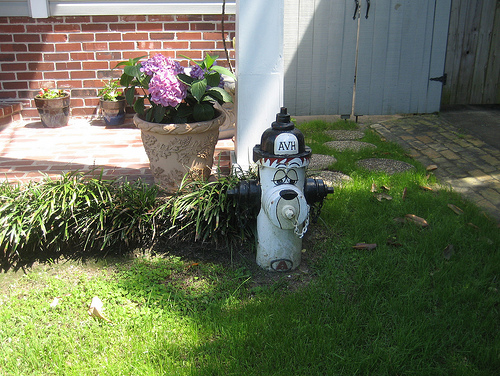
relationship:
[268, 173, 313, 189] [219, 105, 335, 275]
two eyes on fire hydrant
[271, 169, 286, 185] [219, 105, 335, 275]
eye on fire hydrant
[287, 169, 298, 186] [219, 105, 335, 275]
eye on fire hydrant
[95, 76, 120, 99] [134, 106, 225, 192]
plants in a pot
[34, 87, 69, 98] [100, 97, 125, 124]
plants in a pot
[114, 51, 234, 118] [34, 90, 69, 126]
plants in a pot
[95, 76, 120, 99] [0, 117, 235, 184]
plants on patio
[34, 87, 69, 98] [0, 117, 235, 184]
plants on patio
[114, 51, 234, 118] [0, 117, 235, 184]
plants on patio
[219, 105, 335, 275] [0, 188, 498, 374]
fire hydrant in grass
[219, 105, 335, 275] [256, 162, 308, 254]
fire hydrant painted like a dog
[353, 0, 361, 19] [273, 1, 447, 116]
handle on door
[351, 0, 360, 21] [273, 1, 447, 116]
handle on door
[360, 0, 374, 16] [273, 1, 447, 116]
handle on door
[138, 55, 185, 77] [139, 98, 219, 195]
flower in pot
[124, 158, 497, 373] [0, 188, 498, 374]
shadow in grass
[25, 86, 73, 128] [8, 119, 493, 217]
pot on patio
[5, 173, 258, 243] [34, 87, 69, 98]
bush behind plants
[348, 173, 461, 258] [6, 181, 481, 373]
leaves on ground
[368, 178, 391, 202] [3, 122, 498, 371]
dead leaves on grass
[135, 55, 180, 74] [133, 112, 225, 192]
flower in a planter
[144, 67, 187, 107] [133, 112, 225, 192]
flower in a planter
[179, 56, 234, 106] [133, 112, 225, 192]
flower in a planter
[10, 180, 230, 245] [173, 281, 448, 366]
plants in grass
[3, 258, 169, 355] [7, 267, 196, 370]
grass has part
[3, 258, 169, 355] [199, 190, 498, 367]
grass has shadow